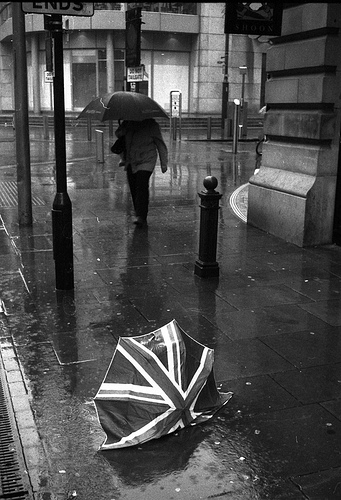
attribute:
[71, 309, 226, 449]
umbrella — broken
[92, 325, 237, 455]
umbrella — broken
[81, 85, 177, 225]
person — one, ambulatory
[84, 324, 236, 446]
umbrella — opened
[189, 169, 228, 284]
post — black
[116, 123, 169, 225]
person — one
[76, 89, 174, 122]
umbrella — opened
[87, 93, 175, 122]
umbrella — one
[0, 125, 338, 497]
sidewalk — wet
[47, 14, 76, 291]
pole — black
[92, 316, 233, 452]
umbrella — crumpled, discarded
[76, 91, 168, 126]
umbrella — black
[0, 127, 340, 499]
ground — wet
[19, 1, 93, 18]
sign — ends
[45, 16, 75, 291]
post — black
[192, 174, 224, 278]
pole — black, small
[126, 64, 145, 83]
sign — street, white, black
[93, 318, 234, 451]
print — British, design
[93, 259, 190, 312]
tiles — wet, sidewalk